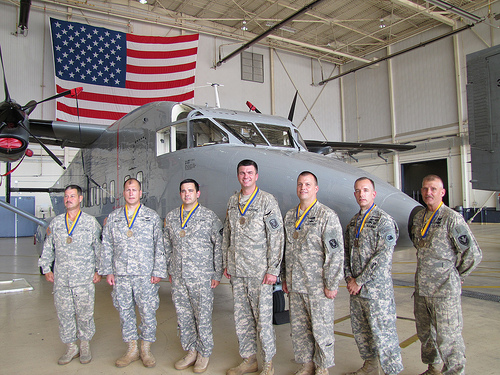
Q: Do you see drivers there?
A: No, there are no drivers.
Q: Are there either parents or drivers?
A: No, there are no drivers or parents.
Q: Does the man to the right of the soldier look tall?
A: Yes, the man is tall.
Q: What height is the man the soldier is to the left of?
A: The man is tall.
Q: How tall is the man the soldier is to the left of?
A: The man is tall.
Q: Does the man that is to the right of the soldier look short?
A: No, the man is tall.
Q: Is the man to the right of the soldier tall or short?
A: The man is tall.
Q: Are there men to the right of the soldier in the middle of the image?
A: Yes, there is a man to the right of the soldier.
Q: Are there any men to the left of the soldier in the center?
A: No, the man is to the right of the soldier.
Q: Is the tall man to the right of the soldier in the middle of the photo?
A: Yes, the man is to the right of the soldier.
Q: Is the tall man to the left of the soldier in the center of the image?
A: No, the man is to the right of the soldier.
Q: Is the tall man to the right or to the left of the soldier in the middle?
A: The man is to the right of the soldier.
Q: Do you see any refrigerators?
A: No, there are no refrigerators.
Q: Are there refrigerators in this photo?
A: No, there are no refrigerators.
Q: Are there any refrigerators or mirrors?
A: No, there are no refrigerators or mirrors.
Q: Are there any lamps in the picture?
A: No, there are no lamps.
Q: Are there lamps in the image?
A: No, there are no lamps.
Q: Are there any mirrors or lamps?
A: No, there are no lamps or mirrors.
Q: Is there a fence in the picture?
A: No, there are no fences.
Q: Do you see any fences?
A: No, there are no fences.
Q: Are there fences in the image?
A: No, there are no fences.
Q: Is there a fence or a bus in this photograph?
A: No, there are no fences or buses.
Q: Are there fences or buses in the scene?
A: No, there are no fences or buses.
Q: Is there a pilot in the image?
A: No, there are no pilots.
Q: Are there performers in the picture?
A: No, there are no performers.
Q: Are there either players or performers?
A: No, there are no performers or players.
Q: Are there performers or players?
A: No, there are no performers or players.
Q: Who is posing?
A: The men are posing.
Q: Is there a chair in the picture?
A: No, there are no chairs.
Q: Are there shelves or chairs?
A: No, there are no chairs or shelves.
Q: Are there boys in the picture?
A: No, there are no boys.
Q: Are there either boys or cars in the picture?
A: No, there are no boys or cars.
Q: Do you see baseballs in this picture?
A: No, there are no baseballs.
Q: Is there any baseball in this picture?
A: No, there are no baseballs.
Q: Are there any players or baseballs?
A: No, there are no baseballs or players.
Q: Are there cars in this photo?
A: No, there are no cars.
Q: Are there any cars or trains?
A: No, there are no cars or trains.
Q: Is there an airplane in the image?
A: Yes, there is an airplane.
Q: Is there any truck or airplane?
A: Yes, there is an airplane.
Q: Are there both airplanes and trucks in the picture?
A: No, there is an airplane but no trucks.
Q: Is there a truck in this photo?
A: No, there are no trucks.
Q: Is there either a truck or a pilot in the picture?
A: No, there are no trucks or pilots.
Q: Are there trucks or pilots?
A: No, there are no trucks or pilots.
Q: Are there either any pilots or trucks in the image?
A: No, there are no trucks or pilots.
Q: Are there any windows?
A: Yes, there are windows.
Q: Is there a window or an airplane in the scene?
A: Yes, there are windows.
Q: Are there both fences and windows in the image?
A: No, there are windows but no fences.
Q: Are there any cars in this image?
A: No, there are no cars.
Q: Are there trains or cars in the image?
A: No, there are no cars or trains.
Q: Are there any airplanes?
A: Yes, there is an airplane.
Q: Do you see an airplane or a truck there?
A: Yes, there is an airplane.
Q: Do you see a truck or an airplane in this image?
A: Yes, there is an airplane.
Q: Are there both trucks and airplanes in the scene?
A: No, there is an airplane but no trucks.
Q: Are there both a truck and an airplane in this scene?
A: No, there is an airplane but no trucks.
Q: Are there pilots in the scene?
A: No, there are no pilots.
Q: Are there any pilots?
A: No, there are no pilots.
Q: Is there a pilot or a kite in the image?
A: No, there are no pilots or kites.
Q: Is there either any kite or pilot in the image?
A: No, there are no pilots or kites.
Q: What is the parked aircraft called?
A: The aircraft is an airplane.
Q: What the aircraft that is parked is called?
A: The aircraft is an airplane.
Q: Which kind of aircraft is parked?
A: The aircraft is an airplane.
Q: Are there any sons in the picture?
A: No, there are no sons.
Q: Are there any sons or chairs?
A: No, there are no sons or chairs.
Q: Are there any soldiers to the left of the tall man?
A: Yes, there is a soldier to the left of the man.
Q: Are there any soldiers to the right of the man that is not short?
A: No, the soldier is to the left of the man.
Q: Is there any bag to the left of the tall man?
A: No, there is a soldier to the left of the man.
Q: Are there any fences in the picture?
A: No, there are no fences.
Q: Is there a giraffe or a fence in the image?
A: No, there are no fences or giraffes.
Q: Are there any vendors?
A: No, there are no vendors.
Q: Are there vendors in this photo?
A: No, there are no vendors.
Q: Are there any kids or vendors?
A: No, there are no vendors or kids.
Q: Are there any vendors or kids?
A: No, there are no vendors or kids.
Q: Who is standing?
A: The soldiers are standing.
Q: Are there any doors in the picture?
A: Yes, there are doors.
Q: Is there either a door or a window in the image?
A: Yes, there are doors.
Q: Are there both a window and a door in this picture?
A: Yes, there are both a door and a window.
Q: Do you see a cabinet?
A: No, there are no cabinets.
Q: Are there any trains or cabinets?
A: No, there are no cabinets or trains.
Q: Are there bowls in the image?
A: No, there are no bowls.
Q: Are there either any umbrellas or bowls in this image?
A: No, there are no bowls or umbrellas.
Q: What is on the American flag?
A: The stars are on the American flag.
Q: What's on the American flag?
A: The stars are on the American flag.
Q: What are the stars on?
A: The stars are on the American flag.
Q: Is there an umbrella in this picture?
A: No, there are no umbrellas.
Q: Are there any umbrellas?
A: No, there are no umbrellas.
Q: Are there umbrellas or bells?
A: No, there are no umbrellas or bells.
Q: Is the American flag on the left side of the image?
A: Yes, the American flag is on the left of the image.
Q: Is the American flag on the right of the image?
A: No, the American flag is on the left of the image.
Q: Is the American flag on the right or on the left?
A: The American flag is on the left of the image.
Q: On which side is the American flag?
A: The American flag is on the left of the image.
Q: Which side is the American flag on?
A: The American flag is on the left of the image.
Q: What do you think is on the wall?
A: The American flag is on the wall.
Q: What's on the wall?
A: The American flag is on the wall.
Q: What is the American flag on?
A: The American flag is on the wall.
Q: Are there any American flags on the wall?
A: Yes, there is an American flag on the wall.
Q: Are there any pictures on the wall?
A: No, there is an American flag on the wall.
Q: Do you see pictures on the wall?
A: No, there is an American flag on the wall.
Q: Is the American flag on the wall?
A: Yes, the American flag is on the wall.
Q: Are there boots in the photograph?
A: Yes, there are boots.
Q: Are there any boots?
A: Yes, there are boots.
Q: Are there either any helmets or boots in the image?
A: Yes, there are boots.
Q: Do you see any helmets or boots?
A: Yes, there are boots.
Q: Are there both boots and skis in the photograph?
A: No, there are boots but no skis.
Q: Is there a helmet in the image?
A: No, there are no helmets.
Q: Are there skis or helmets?
A: No, there are no helmets or skis.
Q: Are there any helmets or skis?
A: No, there are no helmets or skis.